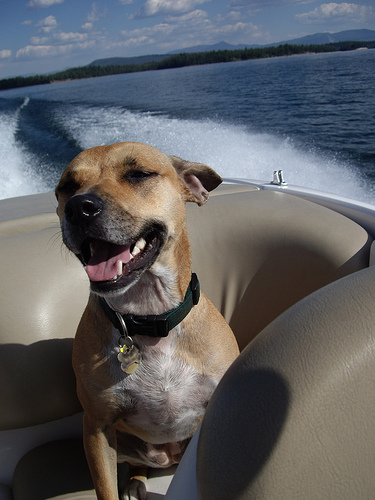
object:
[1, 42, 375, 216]
water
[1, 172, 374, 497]
seat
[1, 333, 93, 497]
shadow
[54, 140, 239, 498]
dog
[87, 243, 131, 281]
tongue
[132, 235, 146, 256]
teeth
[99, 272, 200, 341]
collar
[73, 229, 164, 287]
lip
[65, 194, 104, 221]
nose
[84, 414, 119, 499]
leg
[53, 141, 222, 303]
head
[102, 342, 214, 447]
chest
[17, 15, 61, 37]
cloud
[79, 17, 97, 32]
cloud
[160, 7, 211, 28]
cloud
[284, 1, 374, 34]
cloud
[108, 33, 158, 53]
cloud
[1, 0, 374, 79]
sky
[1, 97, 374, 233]
ocean surf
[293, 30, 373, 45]
hills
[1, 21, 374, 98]
background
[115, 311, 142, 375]
dog tags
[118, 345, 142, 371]
bone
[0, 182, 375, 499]
boat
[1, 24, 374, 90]
sky line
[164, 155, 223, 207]
ear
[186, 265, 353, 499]
edge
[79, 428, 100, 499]
edge